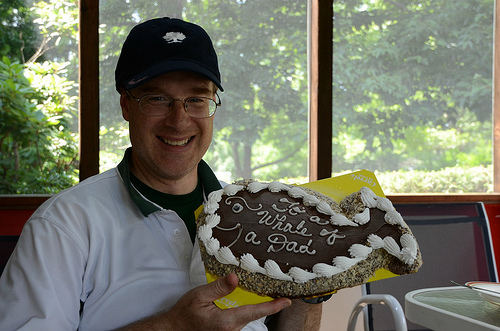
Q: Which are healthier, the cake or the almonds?
A: The almonds are healthier than the cake.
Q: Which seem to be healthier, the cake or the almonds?
A: The almonds are healthier than the cake.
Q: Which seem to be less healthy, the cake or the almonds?
A: The cake are less healthy than the almonds.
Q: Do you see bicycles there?
A: No, there are no bicycles.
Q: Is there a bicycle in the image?
A: No, there are no bicycles.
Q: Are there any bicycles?
A: No, there are no bicycles.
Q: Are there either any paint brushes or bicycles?
A: No, there are no bicycles or paint brushes.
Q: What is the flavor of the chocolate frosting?
A: This is a chocolate frosting.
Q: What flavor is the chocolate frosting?
A: This is a chocolate frosting.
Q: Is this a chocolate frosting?
A: Yes, this is a chocolate frosting.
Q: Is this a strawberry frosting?
A: No, this is a chocolate frosting.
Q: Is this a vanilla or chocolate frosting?
A: This is a chocolate frosting.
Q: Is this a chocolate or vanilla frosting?
A: This is a chocolate frosting.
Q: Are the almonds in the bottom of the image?
A: Yes, the almonds are in the bottom of the image.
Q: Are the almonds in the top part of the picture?
A: No, the almonds are in the bottom of the image.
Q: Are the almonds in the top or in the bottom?
A: The almonds are in the bottom of the image.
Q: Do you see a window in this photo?
A: Yes, there are windows.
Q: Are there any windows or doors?
A: Yes, there are windows.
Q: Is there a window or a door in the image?
A: Yes, there are windows.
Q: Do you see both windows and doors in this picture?
A: No, there are windows but no doors.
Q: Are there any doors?
A: No, there are no doors.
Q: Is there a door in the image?
A: No, there are no doors.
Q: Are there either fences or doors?
A: No, there are no doors or fences.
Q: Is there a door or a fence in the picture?
A: No, there are no doors or fences.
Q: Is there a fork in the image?
A: No, there are no forks.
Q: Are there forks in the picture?
A: No, there are no forks.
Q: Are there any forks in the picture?
A: No, there are no forks.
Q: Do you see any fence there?
A: No, there are no fences.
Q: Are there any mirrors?
A: No, there are no mirrors.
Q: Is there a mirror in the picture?
A: No, there are no mirrors.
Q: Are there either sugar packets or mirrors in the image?
A: No, there are no mirrors or sugar packets.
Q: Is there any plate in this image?
A: Yes, there is a plate.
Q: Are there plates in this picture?
A: Yes, there is a plate.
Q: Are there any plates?
A: Yes, there is a plate.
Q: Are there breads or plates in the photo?
A: Yes, there is a plate.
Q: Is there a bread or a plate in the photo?
A: Yes, there is a plate.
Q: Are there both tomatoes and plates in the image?
A: No, there is a plate but no tomatoes.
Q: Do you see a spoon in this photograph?
A: No, there are no spoons.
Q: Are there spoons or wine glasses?
A: No, there are no spoons or wine glasses.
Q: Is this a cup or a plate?
A: This is a plate.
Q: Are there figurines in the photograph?
A: No, there are no figurines.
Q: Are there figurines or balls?
A: No, there are no figurines or balls.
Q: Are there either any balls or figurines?
A: No, there are no figurines or balls.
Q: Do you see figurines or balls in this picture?
A: No, there are no figurines or balls.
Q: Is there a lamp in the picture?
A: No, there are no lamps.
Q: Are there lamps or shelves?
A: No, there are no lamps or shelves.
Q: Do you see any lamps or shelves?
A: No, there are no lamps or shelves.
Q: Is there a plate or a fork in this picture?
A: Yes, there is a plate.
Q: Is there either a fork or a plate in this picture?
A: Yes, there is a plate.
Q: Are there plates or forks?
A: Yes, there is a plate.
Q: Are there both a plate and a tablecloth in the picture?
A: No, there is a plate but no tablecloths.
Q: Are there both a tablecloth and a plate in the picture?
A: No, there is a plate but no tablecloths.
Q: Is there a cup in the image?
A: No, there are no cups.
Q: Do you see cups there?
A: No, there are no cups.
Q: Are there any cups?
A: No, there are no cups.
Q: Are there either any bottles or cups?
A: No, there are no cups or bottles.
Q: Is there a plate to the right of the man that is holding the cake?
A: Yes, there is a plate to the right of the man.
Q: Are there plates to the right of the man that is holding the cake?
A: Yes, there is a plate to the right of the man.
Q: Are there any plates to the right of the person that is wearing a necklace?
A: Yes, there is a plate to the right of the man.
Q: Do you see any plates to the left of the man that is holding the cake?
A: No, the plate is to the right of the man.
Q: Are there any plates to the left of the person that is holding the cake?
A: No, the plate is to the right of the man.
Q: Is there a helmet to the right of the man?
A: No, there is a plate to the right of the man.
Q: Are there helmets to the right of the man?
A: No, there is a plate to the right of the man.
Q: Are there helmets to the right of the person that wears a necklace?
A: No, there is a plate to the right of the man.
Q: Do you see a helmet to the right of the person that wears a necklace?
A: No, there is a plate to the right of the man.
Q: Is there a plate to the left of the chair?
A: No, the plate is to the right of the chair.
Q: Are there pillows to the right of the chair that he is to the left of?
A: No, there is a plate to the right of the chair.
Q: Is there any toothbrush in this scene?
A: No, there are no toothbrushes.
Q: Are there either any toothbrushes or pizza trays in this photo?
A: No, there are no toothbrushes or pizza trays.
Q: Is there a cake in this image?
A: Yes, there is a cake.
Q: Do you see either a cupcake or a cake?
A: Yes, there is a cake.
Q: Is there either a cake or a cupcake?
A: Yes, there is a cake.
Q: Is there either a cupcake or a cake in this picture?
A: Yes, there is a cake.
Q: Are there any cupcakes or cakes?
A: Yes, there is a cake.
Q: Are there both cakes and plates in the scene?
A: Yes, there are both a cake and a plate.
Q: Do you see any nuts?
A: No, there are no nuts.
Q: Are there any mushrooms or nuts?
A: No, there are no nuts or mushrooms.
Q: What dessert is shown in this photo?
A: The dessert is a cake.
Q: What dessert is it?
A: The dessert is a cake.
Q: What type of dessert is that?
A: This is a cake.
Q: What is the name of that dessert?
A: This is a cake.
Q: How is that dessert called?
A: This is a cake.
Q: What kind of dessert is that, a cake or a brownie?
A: This is a cake.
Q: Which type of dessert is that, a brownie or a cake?
A: This is a cake.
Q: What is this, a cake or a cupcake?
A: This is a cake.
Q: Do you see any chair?
A: Yes, there is a chair.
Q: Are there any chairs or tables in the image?
A: Yes, there is a chair.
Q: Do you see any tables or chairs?
A: Yes, there is a chair.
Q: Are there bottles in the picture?
A: No, there are no bottles.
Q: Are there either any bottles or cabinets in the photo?
A: No, there are no bottles or cabinets.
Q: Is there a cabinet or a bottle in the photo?
A: No, there are no bottles or cabinets.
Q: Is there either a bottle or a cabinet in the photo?
A: No, there are no bottles or cabinets.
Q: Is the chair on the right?
A: Yes, the chair is on the right of the image.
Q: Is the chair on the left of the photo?
A: No, the chair is on the right of the image.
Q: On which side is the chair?
A: The chair is on the right of the image.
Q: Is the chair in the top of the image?
A: No, the chair is in the bottom of the image.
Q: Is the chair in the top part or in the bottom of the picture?
A: The chair is in the bottom of the image.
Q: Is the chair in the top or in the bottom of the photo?
A: The chair is in the bottom of the image.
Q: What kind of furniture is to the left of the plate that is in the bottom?
A: The piece of furniture is a chair.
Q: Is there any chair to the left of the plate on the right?
A: Yes, there is a chair to the left of the plate.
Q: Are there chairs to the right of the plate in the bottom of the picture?
A: No, the chair is to the left of the plate.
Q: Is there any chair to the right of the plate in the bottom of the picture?
A: No, the chair is to the left of the plate.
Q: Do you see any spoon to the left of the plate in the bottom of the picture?
A: No, there is a chair to the left of the plate.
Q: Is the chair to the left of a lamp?
A: No, the chair is to the left of a plate.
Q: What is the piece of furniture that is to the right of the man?
A: The piece of furniture is a chair.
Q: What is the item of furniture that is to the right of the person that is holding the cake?
A: The piece of furniture is a chair.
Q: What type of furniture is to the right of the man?
A: The piece of furniture is a chair.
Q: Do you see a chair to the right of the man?
A: Yes, there is a chair to the right of the man.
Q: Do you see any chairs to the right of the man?
A: Yes, there is a chair to the right of the man.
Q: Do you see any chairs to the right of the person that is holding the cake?
A: Yes, there is a chair to the right of the man.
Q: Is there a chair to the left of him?
A: No, the chair is to the right of the man.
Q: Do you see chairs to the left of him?
A: No, the chair is to the right of the man.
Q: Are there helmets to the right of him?
A: No, there is a chair to the right of the man.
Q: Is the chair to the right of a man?
A: Yes, the chair is to the right of a man.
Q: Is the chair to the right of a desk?
A: No, the chair is to the right of a man.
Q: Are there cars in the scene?
A: No, there are no cars.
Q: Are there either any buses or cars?
A: No, there are no cars or buses.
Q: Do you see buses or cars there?
A: No, there are no cars or buses.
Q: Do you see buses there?
A: No, there are no buses.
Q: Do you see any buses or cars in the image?
A: No, there are no buses or cars.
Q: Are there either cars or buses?
A: No, there are no buses or cars.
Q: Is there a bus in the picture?
A: No, there are no buses.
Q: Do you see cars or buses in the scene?
A: No, there are no buses or cars.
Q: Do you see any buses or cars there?
A: No, there are no buses or cars.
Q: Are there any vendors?
A: No, there are no vendors.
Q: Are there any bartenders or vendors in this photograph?
A: No, there are no vendors or bartenders.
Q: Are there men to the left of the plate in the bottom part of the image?
A: Yes, there is a man to the left of the plate.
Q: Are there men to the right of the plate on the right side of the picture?
A: No, the man is to the left of the plate.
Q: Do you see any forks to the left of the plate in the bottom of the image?
A: No, there is a man to the left of the plate.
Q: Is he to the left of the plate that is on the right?
A: Yes, the man is to the left of the plate.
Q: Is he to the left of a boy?
A: No, the man is to the left of the plate.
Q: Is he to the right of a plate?
A: No, the man is to the left of a plate.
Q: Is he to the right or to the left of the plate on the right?
A: The man is to the left of the plate.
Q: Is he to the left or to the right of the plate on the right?
A: The man is to the left of the plate.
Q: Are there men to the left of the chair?
A: Yes, there is a man to the left of the chair.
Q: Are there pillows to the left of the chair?
A: No, there is a man to the left of the chair.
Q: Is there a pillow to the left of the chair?
A: No, there is a man to the left of the chair.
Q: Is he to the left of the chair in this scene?
A: Yes, the man is to the left of the chair.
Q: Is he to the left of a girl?
A: No, the man is to the left of the chair.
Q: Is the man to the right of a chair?
A: No, the man is to the left of a chair.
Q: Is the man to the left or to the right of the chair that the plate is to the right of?
A: The man is to the left of the chair.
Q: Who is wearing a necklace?
A: The man is wearing a necklace.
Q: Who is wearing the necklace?
A: The man is wearing a necklace.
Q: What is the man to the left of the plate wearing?
A: The man is wearing a necklace.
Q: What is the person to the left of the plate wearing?
A: The man is wearing a necklace.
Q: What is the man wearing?
A: The man is wearing a necklace.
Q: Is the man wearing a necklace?
A: Yes, the man is wearing a necklace.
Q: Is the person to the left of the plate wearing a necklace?
A: Yes, the man is wearing a necklace.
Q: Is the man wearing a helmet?
A: No, the man is wearing a necklace.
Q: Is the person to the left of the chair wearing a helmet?
A: No, the man is wearing a necklace.